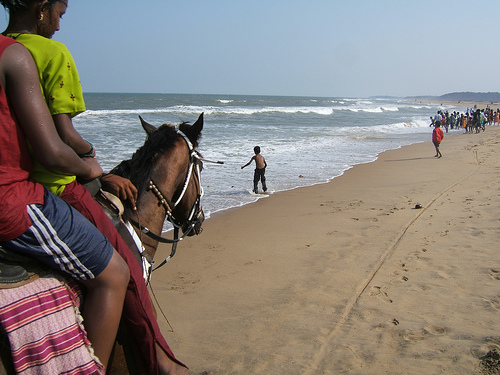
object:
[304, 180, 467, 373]
tracks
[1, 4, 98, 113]
woman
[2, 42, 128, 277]
man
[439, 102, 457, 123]
people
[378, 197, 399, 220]
ground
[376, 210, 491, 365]
sand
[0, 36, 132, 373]
boy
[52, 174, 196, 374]
pants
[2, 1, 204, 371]
girl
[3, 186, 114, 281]
shorts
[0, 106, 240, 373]
horse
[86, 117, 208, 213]
mane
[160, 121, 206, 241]
harness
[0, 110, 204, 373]
horse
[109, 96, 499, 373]
sand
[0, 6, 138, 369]
people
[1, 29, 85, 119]
shirt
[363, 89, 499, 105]
hills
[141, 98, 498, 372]
ocean beach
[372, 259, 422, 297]
footprints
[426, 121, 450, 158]
woman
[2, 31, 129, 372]
person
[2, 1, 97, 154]
person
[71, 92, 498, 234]
ocean waves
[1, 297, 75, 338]
blanket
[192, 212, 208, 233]
nose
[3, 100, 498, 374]
beach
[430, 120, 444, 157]
people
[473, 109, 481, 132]
people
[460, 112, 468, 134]
people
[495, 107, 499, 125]
people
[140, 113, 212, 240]
head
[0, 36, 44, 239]
shirt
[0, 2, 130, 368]
man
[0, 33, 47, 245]
tank top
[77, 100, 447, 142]
waves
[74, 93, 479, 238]
ocean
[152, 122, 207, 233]
bridle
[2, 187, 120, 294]
blue shorts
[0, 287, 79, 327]
stripe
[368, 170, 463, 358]
footprints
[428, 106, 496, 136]
people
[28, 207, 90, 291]
stripe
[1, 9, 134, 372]
person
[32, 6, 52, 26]
earring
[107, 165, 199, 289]
harness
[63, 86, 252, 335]
horse